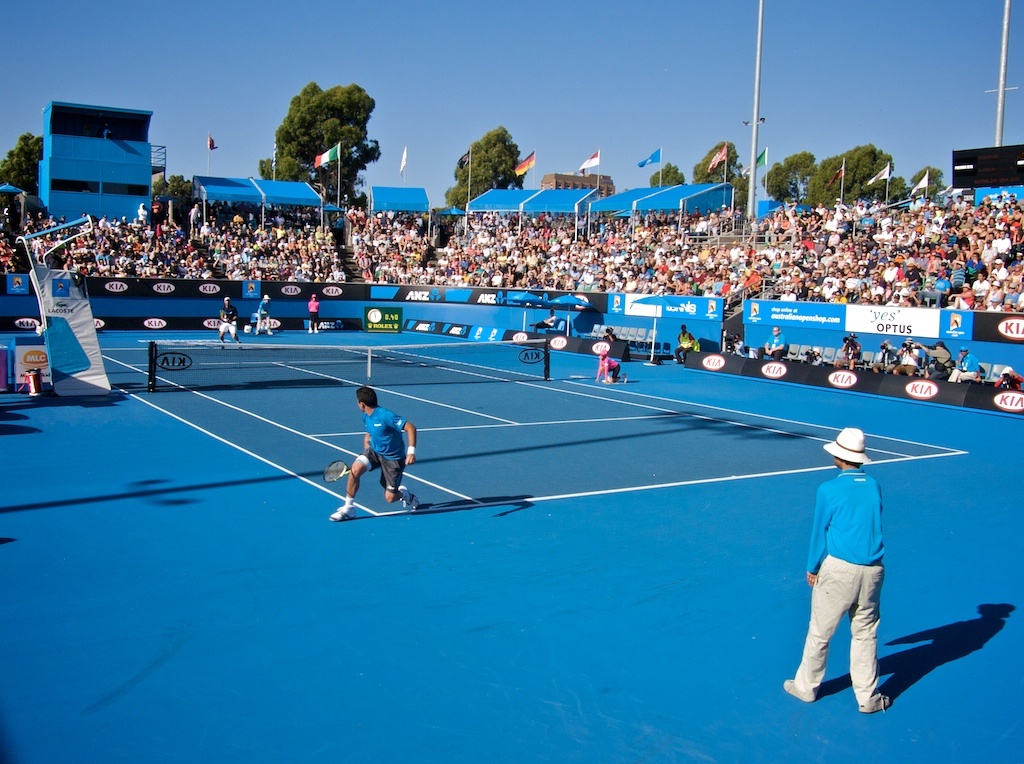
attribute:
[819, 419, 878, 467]
hat —  large white  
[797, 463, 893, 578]
shirt — long sleeve blue  , white   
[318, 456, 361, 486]
racket — large tennis   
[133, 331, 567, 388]
tennis net — long black  , white tennis 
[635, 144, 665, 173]
flag — blue 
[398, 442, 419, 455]
wristband — white 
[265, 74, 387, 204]
tree — tall green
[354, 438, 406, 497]
shorts — man's black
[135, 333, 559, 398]
net — tennis 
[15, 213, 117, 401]
booth — watch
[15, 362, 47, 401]
trash can — trash 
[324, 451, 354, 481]
racket — tennis racket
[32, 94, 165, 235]
area — blue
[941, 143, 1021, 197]
scoreboard — blank, black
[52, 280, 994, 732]
court — end 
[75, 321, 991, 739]
court —  middle 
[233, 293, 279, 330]
ball — tennis 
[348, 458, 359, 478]
hands — mans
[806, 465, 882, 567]
sweater — teal